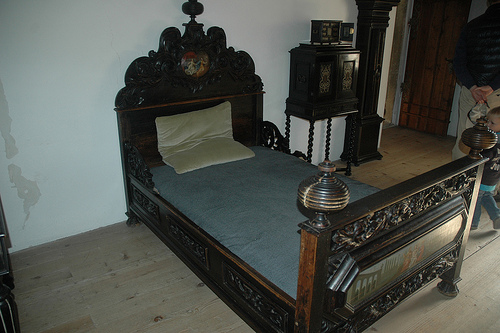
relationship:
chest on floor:
[285, 41, 360, 122] [29, 248, 179, 330]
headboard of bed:
[112, 0, 265, 170] [115, 22, 491, 329]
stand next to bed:
[284, 42, 360, 175] [115, 22, 491, 329]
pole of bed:
[295, 157, 352, 230] [115, 22, 491, 329]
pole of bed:
[462, 116, 499, 158] [115, 22, 491, 329]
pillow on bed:
[158, 119, 240, 172] [115, 0, 497, 332]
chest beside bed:
[285, 41, 360, 176] [115, 22, 491, 329]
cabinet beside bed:
[291, 42, 366, 117] [115, 22, 491, 329]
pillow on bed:
[155, 100, 255, 174] [101, 2, 494, 331]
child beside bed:
[472, 110, 498, 215] [122, 6, 482, 302]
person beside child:
[454, 4, 499, 165] [470, 105, 499, 231]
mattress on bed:
[149, 140, 383, 297] [115, 22, 491, 329]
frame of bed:
[106, 2, 498, 324] [115, 0, 497, 332]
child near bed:
[470, 105, 499, 231] [115, 22, 491, 329]